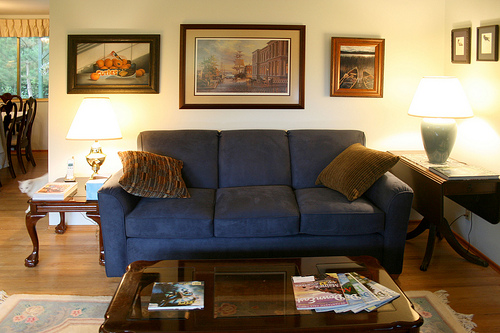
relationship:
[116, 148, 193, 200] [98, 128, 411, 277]
pillow on top of couch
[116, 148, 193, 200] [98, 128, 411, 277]
pillow on right side of couch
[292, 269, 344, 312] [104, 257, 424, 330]
magazine on left side of center table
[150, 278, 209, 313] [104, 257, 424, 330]
magazine on right side of center table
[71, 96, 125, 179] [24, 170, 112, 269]
table lamp on top of end table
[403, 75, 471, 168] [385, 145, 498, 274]
table lamp on top of side table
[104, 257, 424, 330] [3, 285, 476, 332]
center table placed on rug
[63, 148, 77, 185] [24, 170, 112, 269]
bottle of water on top of end table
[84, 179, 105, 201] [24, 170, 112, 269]
box on top of end table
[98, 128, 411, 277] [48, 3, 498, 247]
couch against wall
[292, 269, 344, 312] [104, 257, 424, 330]
magazine on top of center table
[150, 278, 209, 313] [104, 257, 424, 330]
magazine on top of center table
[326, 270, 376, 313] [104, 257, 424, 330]
magazine on top of center table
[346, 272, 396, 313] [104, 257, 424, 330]
magazine on top of center table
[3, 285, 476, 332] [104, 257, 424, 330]
rug underneath center table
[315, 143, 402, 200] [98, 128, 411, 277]
pillow on top of couch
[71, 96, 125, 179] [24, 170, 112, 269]
table lamp sitting on end table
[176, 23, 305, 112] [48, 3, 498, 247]
art print hanging from wall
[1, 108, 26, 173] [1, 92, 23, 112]
table surrounded by chair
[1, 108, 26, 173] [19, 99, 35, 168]
table surrounded by chair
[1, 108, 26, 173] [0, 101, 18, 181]
table surrounded by chair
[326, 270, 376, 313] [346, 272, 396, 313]
magazine next to magazine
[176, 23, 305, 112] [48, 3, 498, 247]
art print hagning on wall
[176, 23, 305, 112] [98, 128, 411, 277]
art print hanging above couch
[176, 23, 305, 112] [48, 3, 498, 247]
art print hanging on wall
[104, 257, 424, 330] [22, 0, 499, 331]
center table inside living room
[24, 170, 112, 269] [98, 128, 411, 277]
end table sitting beside couch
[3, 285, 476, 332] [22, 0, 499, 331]
rug inside living room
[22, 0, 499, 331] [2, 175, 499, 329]
living room has floor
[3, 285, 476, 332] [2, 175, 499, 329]
rug on top of floor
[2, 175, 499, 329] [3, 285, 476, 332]
floor has rug